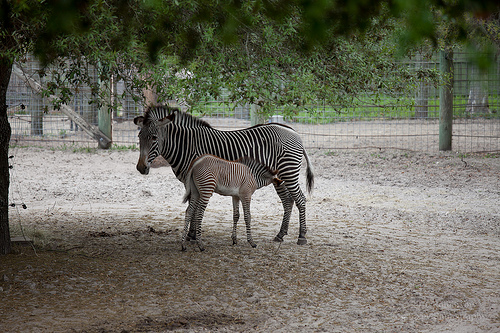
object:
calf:
[180, 155, 286, 251]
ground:
[336, 230, 448, 330]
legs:
[277, 155, 307, 237]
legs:
[239, 195, 252, 240]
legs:
[196, 183, 216, 246]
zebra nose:
[136, 165, 147, 170]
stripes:
[197, 177, 217, 182]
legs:
[272, 177, 295, 234]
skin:
[219, 169, 251, 180]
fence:
[310, 104, 497, 153]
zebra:
[132, 102, 314, 252]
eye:
[152, 135, 158, 140]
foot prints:
[185, 254, 239, 301]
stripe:
[278, 163, 300, 170]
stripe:
[279, 173, 299, 180]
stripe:
[199, 183, 216, 186]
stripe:
[253, 129, 264, 165]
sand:
[37, 242, 88, 331]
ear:
[159, 112, 176, 124]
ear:
[134, 116, 145, 128]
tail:
[303, 148, 315, 198]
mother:
[133, 102, 315, 245]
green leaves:
[155, 43, 187, 68]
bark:
[0, 63, 12, 77]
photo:
[0, 1, 499, 333]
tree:
[381, 1, 496, 151]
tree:
[0, 3, 325, 124]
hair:
[143, 102, 212, 128]